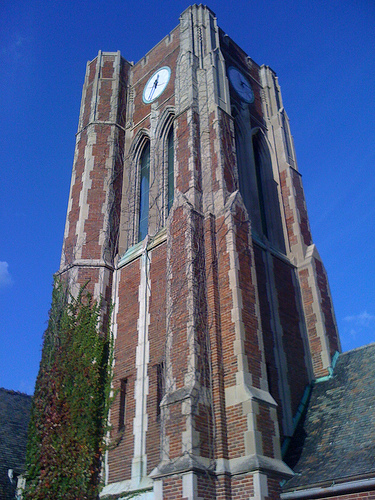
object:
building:
[69, 7, 349, 334]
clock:
[225, 61, 258, 105]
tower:
[15, 5, 338, 491]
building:
[26, 2, 341, 498]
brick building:
[20, 2, 348, 497]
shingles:
[335, 406, 373, 475]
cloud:
[1, 258, 16, 288]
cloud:
[335, 304, 373, 349]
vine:
[152, 193, 206, 486]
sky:
[305, 100, 351, 169]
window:
[135, 136, 150, 244]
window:
[162, 120, 175, 223]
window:
[252, 127, 269, 242]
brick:
[76, 54, 115, 307]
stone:
[128, 246, 155, 478]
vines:
[28, 267, 108, 495]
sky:
[1, 4, 111, 314]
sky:
[74, 6, 195, 49]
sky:
[230, 4, 374, 46]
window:
[116, 364, 130, 438]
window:
[150, 107, 183, 220]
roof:
[311, 355, 374, 478]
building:
[35, 3, 374, 498]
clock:
[140, 64, 173, 103]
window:
[155, 361, 167, 423]